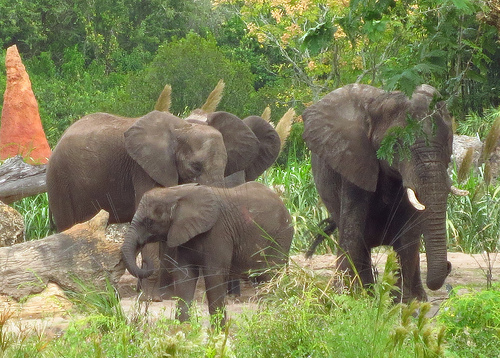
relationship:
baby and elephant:
[122, 181, 294, 321] [302, 83, 453, 307]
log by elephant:
[2, 209, 127, 319] [302, 83, 453, 307]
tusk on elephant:
[405, 185, 426, 212] [302, 83, 453, 307]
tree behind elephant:
[145, 30, 257, 122] [302, 83, 453, 307]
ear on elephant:
[299, 81, 379, 192] [302, 83, 453, 307]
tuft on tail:
[49, 221, 57, 231] [45, 203, 55, 236]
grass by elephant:
[0, 290, 498, 357] [302, 83, 453, 307]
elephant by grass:
[302, 83, 453, 307] [0, 290, 498, 357]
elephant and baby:
[302, 83, 453, 307] [122, 181, 294, 321]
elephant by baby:
[302, 83, 453, 307] [122, 181, 294, 321]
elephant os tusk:
[302, 83, 453, 307] [405, 185, 426, 212]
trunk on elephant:
[415, 208, 452, 289] [302, 83, 453, 307]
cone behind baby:
[2, 42, 53, 165] [122, 181, 294, 321]